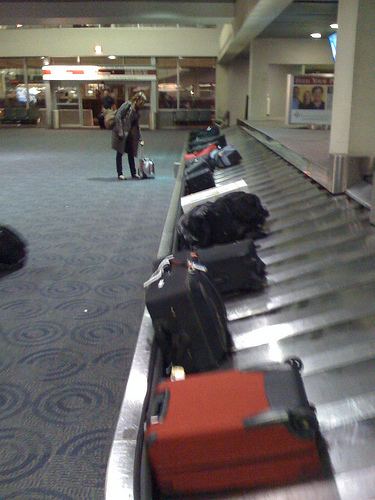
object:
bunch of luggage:
[174, 176, 270, 299]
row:
[143, 123, 334, 467]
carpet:
[62, 204, 102, 239]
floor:
[0, 127, 188, 499]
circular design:
[17, 345, 89, 384]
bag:
[141, 350, 325, 497]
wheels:
[293, 356, 303, 370]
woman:
[111, 89, 157, 181]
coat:
[111, 99, 143, 160]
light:
[309, 31, 323, 39]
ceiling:
[257, 0, 339, 41]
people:
[311, 85, 325, 110]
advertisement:
[284, 74, 334, 131]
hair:
[130, 91, 148, 110]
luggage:
[183, 140, 219, 161]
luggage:
[142, 249, 237, 374]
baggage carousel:
[104, 121, 375, 500]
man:
[101, 88, 117, 129]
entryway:
[92, 79, 125, 130]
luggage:
[137, 141, 156, 180]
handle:
[140, 140, 146, 157]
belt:
[241, 156, 277, 182]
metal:
[281, 179, 299, 283]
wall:
[0, 26, 222, 59]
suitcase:
[195, 236, 269, 295]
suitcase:
[210, 143, 243, 168]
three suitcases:
[143, 190, 272, 377]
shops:
[39, 94, 44, 96]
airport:
[0, 0, 375, 210]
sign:
[157, 82, 178, 92]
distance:
[185, 143, 269, 171]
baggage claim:
[167, 107, 374, 500]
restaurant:
[0, 56, 217, 130]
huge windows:
[1, 65, 29, 111]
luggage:
[101, 107, 118, 131]